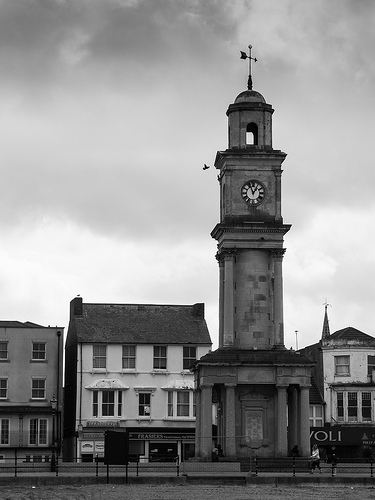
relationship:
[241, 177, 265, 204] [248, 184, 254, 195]
clockface with hands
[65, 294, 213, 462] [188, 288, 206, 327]
building with canopied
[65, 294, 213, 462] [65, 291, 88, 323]
building with canopied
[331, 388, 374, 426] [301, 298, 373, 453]
window on building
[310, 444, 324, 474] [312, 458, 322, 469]
children wearing pants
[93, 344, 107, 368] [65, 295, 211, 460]
window on building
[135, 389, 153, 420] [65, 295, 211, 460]
window on building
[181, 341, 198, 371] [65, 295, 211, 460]
window on building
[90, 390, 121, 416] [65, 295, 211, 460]
window on building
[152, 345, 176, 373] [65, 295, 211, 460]
window on building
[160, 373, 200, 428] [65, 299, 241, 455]
window on building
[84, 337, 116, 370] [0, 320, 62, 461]
window on building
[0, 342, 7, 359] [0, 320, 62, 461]
window on building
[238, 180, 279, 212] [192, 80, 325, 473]
clock on tower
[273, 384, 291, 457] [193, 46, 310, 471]
pillar in clock tower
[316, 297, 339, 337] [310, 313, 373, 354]
decoration on roof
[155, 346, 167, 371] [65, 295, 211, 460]
window on building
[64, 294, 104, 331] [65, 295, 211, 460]
chimney on building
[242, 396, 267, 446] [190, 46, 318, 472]
door on clock tower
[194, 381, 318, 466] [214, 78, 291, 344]
pillars are under tower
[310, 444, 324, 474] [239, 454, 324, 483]
children walking near bench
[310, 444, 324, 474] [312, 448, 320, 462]
children wearing shirt